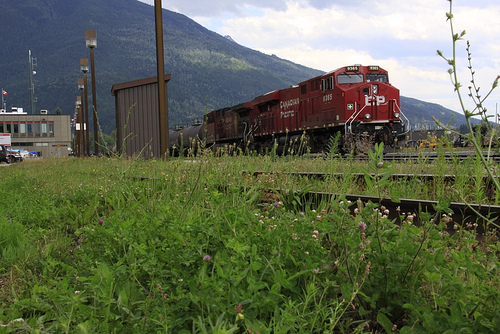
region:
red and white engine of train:
[316, 67, 402, 131]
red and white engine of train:
[278, 85, 334, 124]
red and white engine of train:
[197, 112, 304, 134]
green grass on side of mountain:
[33, 5, 78, 105]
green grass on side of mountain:
[171, 34, 238, 88]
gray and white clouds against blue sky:
[240, 7, 420, 52]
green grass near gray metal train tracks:
[312, 146, 484, 223]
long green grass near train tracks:
[25, 195, 264, 321]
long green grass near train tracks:
[240, 206, 475, 316]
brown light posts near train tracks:
[72, 30, 166, 160]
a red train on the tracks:
[168, 52, 405, 160]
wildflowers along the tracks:
[170, 114, 409, 276]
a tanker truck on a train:
[176, 110, 210, 152]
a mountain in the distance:
[2, 1, 480, 147]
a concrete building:
[0, 104, 77, 164]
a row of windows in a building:
[0, 119, 61, 139]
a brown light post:
[85, 27, 109, 152]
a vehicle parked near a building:
[0, 139, 21, 166]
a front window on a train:
[334, 69, 368, 85]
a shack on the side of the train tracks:
[115, 65, 175, 167]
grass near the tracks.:
[134, 203, 211, 252]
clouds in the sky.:
[292, 14, 327, 27]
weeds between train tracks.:
[357, 179, 438, 187]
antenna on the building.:
[26, 45, 43, 95]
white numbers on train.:
[319, 91, 333, 102]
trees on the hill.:
[197, 77, 248, 94]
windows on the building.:
[24, 125, 50, 131]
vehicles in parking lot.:
[7, 144, 22, 159]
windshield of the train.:
[338, 77, 359, 81]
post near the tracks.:
[90, 26, 95, 171]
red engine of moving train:
[306, 62, 409, 135]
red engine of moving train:
[226, 82, 318, 129]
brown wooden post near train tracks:
[106, 73, 193, 145]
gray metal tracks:
[294, 141, 482, 218]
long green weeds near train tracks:
[13, 202, 265, 321]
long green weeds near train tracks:
[254, 207, 471, 323]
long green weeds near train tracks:
[45, 153, 285, 212]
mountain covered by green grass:
[171, 36, 232, 96]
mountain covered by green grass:
[41, 10, 69, 105]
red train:
[200, 61, 410, 153]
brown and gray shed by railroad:
[109, 71, 172, 163]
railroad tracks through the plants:
[172, 149, 497, 232]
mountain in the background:
[2, 0, 496, 141]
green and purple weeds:
[6, 162, 491, 332]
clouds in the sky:
[204, 7, 485, 49]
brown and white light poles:
[67, 29, 102, 158]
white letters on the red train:
[363, 91, 388, 111]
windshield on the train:
[330, 71, 388, 87]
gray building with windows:
[2, 104, 76, 161]